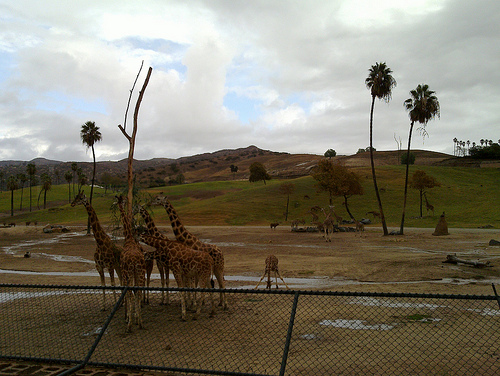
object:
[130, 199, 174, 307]
giraffe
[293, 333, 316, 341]
water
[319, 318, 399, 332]
water puddle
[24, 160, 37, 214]
palm tree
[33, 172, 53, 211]
palm tree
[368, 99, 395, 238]
tree trunk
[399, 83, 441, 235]
palm tree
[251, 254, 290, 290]
unbalanced-baby giraffe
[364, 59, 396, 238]
tallest palm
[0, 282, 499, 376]
chainlink fence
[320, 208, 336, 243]
adult kangaroo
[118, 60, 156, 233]
tree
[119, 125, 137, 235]
feeder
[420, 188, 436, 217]
adult giraffe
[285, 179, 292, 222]
tiniest palm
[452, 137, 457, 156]
palm trees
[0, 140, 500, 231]
small mountain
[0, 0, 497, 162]
clouds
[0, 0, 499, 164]
sky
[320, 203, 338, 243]
giraffe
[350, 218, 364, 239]
giraffe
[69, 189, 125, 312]
giraffe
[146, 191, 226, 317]
giraffe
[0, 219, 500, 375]
enclosure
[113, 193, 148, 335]
giraffe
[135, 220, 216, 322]
giraffe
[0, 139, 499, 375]
zoo